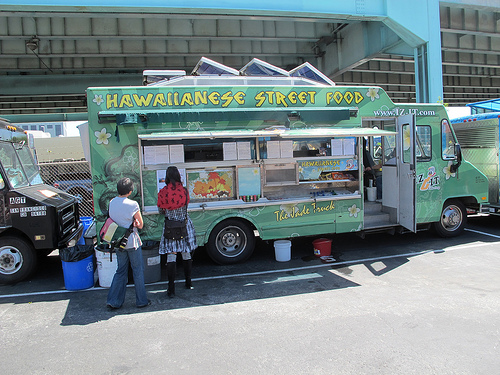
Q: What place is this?
A: It is a street.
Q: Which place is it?
A: It is a street.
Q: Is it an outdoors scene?
A: Yes, it is outdoors.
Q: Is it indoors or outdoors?
A: It is outdoors.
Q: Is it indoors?
A: No, it is outdoors.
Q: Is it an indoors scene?
A: No, it is outdoors.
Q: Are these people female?
A: Yes, all the people are female.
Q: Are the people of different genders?
A: No, all the people are female.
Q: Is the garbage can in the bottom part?
A: Yes, the garbage can is in the bottom of the image.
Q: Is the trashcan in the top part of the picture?
A: No, the trashcan is in the bottom of the image.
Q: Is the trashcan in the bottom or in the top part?
A: The trashcan is in the bottom of the image.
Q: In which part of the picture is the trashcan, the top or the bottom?
A: The trashcan is in the bottom of the image.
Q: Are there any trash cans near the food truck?
A: Yes, there is a trash can near the food truck.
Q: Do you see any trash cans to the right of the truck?
A: Yes, there is a trash can to the right of the truck.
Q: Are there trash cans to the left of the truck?
A: No, the trash can is to the right of the truck.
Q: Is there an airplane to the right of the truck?
A: No, there is a trash can to the right of the truck.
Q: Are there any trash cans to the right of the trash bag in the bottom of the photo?
A: Yes, there is a trash can to the right of the trash bag.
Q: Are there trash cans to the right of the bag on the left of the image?
A: Yes, there is a trash can to the right of the trash bag.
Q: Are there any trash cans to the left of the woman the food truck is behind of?
A: Yes, there is a trash can to the left of the woman.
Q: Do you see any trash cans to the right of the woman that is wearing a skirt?
A: No, the trash can is to the left of the woman.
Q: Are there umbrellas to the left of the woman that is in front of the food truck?
A: No, there is a trash can to the left of the woman.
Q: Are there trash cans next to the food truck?
A: Yes, there is a trash can next to the food truck.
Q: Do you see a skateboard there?
A: No, there are no skateboards.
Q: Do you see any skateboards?
A: No, there are no skateboards.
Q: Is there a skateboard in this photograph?
A: No, there are no skateboards.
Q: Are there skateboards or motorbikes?
A: No, there are no skateboards or motorbikes.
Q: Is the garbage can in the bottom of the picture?
A: Yes, the garbage can is in the bottom of the image.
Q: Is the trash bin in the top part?
A: No, the trash bin is in the bottom of the image.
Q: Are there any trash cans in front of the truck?
A: Yes, there is a trash can in front of the truck.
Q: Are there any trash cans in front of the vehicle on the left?
A: Yes, there is a trash can in front of the truck.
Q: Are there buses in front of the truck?
A: No, there is a trash can in front of the truck.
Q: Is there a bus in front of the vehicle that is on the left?
A: No, there is a trash can in front of the truck.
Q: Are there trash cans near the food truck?
A: Yes, there is a trash can near the food truck.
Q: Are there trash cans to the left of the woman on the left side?
A: Yes, there is a trash can to the left of the woman.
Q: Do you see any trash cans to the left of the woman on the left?
A: Yes, there is a trash can to the left of the woman.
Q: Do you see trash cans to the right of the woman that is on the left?
A: No, the trash can is to the left of the woman.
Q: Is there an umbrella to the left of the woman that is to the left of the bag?
A: No, there is a trash can to the left of the woman.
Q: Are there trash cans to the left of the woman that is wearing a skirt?
A: Yes, there is a trash can to the left of the woman.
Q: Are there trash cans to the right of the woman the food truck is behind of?
A: No, the trash can is to the left of the woman.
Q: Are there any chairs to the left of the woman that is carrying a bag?
A: No, there is a trash can to the left of the woman.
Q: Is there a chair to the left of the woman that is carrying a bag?
A: No, there is a trash can to the left of the woman.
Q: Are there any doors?
A: Yes, there is a door.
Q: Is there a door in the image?
A: Yes, there is a door.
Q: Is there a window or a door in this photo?
A: Yes, there is a door.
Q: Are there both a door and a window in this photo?
A: Yes, there are both a door and a window.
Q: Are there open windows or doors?
A: Yes, there is an open door.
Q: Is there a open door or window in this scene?
A: Yes, there is an open door.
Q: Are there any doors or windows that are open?
A: Yes, the door is open.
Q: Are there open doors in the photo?
A: Yes, there is an open door.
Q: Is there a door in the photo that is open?
A: Yes, there is a door that is open.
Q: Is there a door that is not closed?
A: Yes, there is a open door.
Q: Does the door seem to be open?
A: Yes, the door is open.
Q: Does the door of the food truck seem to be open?
A: Yes, the door is open.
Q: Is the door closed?
A: No, the door is open.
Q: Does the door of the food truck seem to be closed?
A: No, the door is open.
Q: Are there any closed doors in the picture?
A: No, there is a door but it is open.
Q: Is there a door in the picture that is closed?
A: No, there is a door but it is open.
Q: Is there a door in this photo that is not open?
A: No, there is a door but it is open.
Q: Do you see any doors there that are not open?
A: No, there is a door but it is open.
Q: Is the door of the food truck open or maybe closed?
A: The door is open.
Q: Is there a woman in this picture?
A: Yes, there is a woman.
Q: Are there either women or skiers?
A: Yes, there is a woman.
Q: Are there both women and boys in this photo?
A: No, there is a woman but no boys.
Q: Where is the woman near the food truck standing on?
A: The woman is standing on the street.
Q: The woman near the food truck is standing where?
A: The woman is standing on the street.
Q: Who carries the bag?
A: The woman carries the bag.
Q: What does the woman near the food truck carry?
A: The woman carries a bag.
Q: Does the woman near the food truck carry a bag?
A: Yes, the woman carries a bag.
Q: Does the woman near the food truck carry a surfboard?
A: No, the woman carries a bag.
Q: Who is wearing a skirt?
A: The woman is wearing a skirt.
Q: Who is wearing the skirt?
A: The woman is wearing a skirt.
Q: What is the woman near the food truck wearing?
A: The woman is wearing a skirt.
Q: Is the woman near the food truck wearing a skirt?
A: Yes, the woman is wearing a skirt.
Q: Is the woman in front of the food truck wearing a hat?
A: No, the woman is wearing a skirt.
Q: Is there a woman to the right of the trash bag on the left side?
A: Yes, there is a woman to the right of the trash bag.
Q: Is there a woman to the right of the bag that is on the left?
A: Yes, there is a woman to the right of the trash bag.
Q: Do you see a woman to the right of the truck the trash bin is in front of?
A: Yes, there is a woman to the right of the truck.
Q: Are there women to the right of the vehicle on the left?
A: Yes, there is a woman to the right of the truck.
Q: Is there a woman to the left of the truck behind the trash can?
A: No, the woman is to the right of the truck.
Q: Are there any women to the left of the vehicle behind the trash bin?
A: No, the woman is to the right of the truck.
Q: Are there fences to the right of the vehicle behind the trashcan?
A: No, there is a woman to the right of the truck.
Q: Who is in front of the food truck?
A: The woman is in front of the food truck.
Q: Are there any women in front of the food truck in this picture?
A: Yes, there is a woman in front of the food truck.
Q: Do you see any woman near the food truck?
A: Yes, there is a woman near the food truck.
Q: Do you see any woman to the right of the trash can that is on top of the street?
A: Yes, there is a woman to the right of the garbage bin.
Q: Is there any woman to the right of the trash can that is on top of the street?
A: Yes, there is a woman to the right of the garbage bin.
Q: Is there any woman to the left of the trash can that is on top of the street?
A: No, the woman is to the right of the trash can.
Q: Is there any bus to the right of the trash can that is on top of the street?
A: No, there is a woman to the right of the trash bin.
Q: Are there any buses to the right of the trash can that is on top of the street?
A: No, there is a woman to the right of the trash bin.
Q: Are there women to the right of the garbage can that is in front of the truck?
A: Yes, there is a woman to the right of the garbage bin.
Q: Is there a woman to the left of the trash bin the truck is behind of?
A: No, the woman is to the right of the garbage bin.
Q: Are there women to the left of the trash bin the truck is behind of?
A: No, the woman is to the right of the garbage bin.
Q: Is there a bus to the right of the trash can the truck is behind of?
A: No, there is a woman to the right of the garbage bin.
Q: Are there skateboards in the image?
A: No, there are no skateboards.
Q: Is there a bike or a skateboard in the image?
A: No, there are no skateboards or bikes.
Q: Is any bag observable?
A: Yes, there is a bag.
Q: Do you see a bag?
A: Yes, there is a bag.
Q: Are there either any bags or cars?
A: Yes, there is a bag.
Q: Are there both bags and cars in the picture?
A: No, there is a bag but no cars.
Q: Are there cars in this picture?
A: No, there are no cars.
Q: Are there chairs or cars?
A: No, there are no cars or chairs.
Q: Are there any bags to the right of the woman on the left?
A: Yes, there is a bag to the right of the woman.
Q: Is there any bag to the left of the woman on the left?
A: No, the bag is to the right of the woman.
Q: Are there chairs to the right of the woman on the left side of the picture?
A: No, there is a bag to the right of the woman.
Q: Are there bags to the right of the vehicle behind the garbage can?
A: Yes, there is a bag to the right of the truck.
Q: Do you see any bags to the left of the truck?
A: No, the bag is to the right of the truck.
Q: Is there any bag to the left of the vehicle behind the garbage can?
A: No, the bag is to the right of the truck.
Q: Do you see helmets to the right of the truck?
A: No, there is a bag to the right of the truck.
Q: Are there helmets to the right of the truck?
A: No, there is a bag to the right of the truck.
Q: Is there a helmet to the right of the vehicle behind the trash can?
A: No, there is a bag to the right of the truck.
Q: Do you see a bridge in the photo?
A: Yes, there is a bridge.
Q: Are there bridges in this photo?
A: Yes, there is a bridge.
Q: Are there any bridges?
A: Yes, there is a bridge.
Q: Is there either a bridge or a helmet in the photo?
A: Yes, there is a bridge.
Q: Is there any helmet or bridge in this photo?
A: Yes, there is a bridge.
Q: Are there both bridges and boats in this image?
A: No, there is a bridge but no boats.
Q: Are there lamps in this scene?
A: No, there are no lamps.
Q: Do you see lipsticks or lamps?
A: No, there are no lamps or lipsticks.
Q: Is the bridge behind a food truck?
A: Yes, the bridge is behind a food truck.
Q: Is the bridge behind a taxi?
A: No, the bridge is behind a food truck.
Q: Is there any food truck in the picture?
A: Yes, there is a food truck.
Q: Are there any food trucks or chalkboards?
A: Yes, there is a food truck.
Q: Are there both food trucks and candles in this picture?
A: No, there is a food truck but no candles.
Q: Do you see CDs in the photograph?
A: No, there are no cds.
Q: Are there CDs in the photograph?
A: No, there are no cds.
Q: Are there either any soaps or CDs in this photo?
A: No, there are no CDs or soaps.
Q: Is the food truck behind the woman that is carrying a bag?
A: Yes, the food truck is behind the woman.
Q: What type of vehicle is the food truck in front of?
A: The food truck is in front of the truck.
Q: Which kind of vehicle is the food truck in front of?
A: The food truck is in front of the truck.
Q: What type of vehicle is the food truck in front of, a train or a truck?
A: The food truck is in front of a truck.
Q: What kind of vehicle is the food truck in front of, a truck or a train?
A: The food truck is in front of a truck.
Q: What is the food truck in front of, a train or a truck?
A: The food truck is in front of a truck.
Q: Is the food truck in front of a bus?
A: No, the food truck is in front of the truck.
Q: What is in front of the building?
A: The food truck is in front of the building.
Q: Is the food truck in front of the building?
A: Yes, the food truck is in front of the building.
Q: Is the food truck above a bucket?
A: Yes, the food truck is above a bucket.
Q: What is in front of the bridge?
A: The food truck is in front of the bridge.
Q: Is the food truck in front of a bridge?
A: Yes, the food truck is in front of a bridge.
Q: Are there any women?
A: Yes, there is a woman.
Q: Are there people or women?
A: Yes, there is a woman.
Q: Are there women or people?
A: Yes, there is a woman.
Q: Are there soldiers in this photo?
A: No, there are no soldiers.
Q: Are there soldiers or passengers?
A: No, there are no soldiers or passengers.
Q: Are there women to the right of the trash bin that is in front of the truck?
A: Yes, there is a woman to the right of the trash can.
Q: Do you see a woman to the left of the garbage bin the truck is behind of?
A: No, the woman is to the right of the garbage can.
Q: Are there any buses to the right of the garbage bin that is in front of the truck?
A: No, there is a woman to the right of the garbage bin.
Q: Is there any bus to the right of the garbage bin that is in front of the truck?
A: No, there is a woman to the right of the garbage bin.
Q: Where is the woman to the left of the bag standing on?
A: The woman is standing on the street.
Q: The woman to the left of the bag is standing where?
A: The woman is standing on the street.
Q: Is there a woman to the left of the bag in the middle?
A: Yes, there is a woman to the left of the bag.